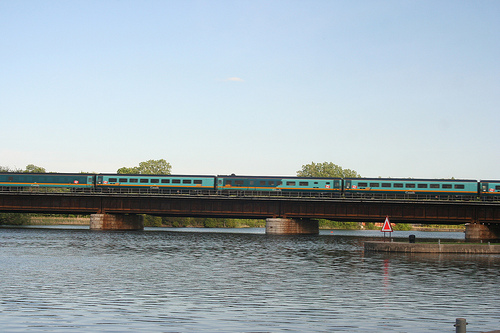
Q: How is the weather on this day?
A: It is clear.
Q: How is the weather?
A: It is clear.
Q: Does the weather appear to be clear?
A: Yes, it is clear.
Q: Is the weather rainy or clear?
A: It is clear.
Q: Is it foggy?
A: No, it is clear.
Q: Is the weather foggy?
A: No, it is clear.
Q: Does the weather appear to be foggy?
A: No, it is clear.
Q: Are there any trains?
A: Yes, there is a train.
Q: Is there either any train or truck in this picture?
A: Yes, there is a train.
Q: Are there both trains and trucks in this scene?
A: No, there is a train but no trucks.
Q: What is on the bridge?
A: The train is on the bridge.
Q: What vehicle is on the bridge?
A: The vehicle is a train.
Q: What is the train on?
A: The train is on the bridge.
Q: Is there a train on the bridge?
A: Yes, there is a train on the bridge.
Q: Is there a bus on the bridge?
A: No, there is a train on the bridge.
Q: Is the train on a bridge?
A: Yes, the train is on a bridge.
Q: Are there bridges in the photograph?
A: Yes, there is a bridge.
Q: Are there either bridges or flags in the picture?
A: Yes, there is a bridge.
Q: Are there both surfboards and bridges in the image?
A: No, there is a bridge but no surfboards.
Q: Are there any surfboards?
A: No, there are no surfboards.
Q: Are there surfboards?
A: No, there are no surfboards.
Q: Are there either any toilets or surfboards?
A: No, there are no surfboards or toilets.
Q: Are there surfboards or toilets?
A: No, there are no surfboards or toilets.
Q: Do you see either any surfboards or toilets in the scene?
A: No, there are no surfboards or toilets.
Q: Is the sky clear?
A: Yes, the sky is clear.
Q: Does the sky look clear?
A: Yes, the sky is clear.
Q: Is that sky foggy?
A: No, the sky is clear.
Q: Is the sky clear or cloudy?
A: The sky is clear.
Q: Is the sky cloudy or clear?
A: The sky is clear.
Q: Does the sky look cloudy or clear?
A: The sky is clear.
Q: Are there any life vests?
A: No, there are no life vests.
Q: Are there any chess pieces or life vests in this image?
A: No, there are no life vests or chess pieces.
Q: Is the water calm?
A: Yes, the water is calm.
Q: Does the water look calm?
A: Yes, the water is calm.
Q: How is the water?
A: The water is calm.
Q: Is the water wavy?
A: No, the water is calm.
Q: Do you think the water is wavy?
A: No, the water is calm.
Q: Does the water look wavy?
A: No, the water is calm.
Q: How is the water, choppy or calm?
A: The water is calm.